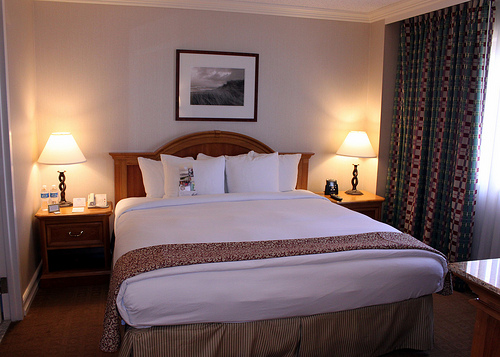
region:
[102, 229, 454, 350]
Brown strip across the bed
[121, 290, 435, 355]
Brown bottom of bed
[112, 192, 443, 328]
White top of bed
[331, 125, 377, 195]
Lamp on night stand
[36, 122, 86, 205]
Lamp on night stand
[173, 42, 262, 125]
Black and white picture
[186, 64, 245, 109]
Black and white picture of mountains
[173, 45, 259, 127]
Black rectangular picture frame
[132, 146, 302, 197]
A group of white pillows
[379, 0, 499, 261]
Multi colored long window curtains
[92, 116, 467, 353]
A bed in the foreground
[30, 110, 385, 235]
Two small lamps on each side of the bed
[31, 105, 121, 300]
Lamp is on a small table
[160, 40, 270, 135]
A picture frame is on the wall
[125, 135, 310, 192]
White pillows are on the bed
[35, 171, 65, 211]
Two water bottles are on the table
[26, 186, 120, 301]
Table is made of wood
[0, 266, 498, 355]
The carpet on the floor is brown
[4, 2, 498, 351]
Photo is of a small bedroom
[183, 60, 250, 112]
Black and white Photograph is inside the picture frame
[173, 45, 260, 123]
Framed artwork hung over a bed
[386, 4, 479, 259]
Curtains in a hotel room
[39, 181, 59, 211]
Two bottles of water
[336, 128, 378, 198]
A lit table lamp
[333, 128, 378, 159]
A white lamp shade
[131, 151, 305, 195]
Pillows with white pillow cases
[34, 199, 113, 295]
A wooden bedside table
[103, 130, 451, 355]
A neatly made bed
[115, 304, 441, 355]
A striped bed skirt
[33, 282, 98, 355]
A brown carpet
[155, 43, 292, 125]
a picture on the wall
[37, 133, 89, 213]
a small lamp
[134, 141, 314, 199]
pillows on a bed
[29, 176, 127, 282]
an endtable next to a bed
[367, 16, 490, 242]
curtains over a window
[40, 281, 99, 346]
carpeting on the floor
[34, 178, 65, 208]
two bottles of water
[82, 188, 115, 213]
a telephone on an endtable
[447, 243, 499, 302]
the edge of a table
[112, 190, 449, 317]
a mattress on a bed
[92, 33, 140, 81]
this is the wall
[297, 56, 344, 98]
the wall is white in color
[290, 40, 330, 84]
the wall is clean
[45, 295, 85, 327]
this is the floor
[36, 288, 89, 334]
the floor has a carpet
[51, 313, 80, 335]
the carpet is brown in color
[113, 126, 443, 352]
this is a bed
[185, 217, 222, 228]
this is a sheet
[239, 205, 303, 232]
the sheets are white in color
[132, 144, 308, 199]
these are some pillows